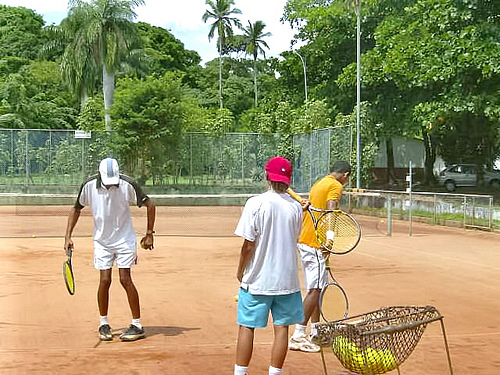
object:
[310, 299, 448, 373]
basket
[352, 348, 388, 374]
tennis balls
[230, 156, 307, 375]
boy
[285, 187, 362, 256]
tennis racket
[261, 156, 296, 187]
cap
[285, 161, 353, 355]
boy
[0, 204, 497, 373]
dirt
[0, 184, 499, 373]
tennis court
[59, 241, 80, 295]
racket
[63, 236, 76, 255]
hand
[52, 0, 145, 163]
tree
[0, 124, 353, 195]
fence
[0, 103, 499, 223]
perimeter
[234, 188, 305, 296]
shirt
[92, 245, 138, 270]
shorts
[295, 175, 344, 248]
shirt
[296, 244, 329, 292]
short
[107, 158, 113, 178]
stripe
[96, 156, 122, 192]
cap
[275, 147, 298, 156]
backwards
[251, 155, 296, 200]
wearing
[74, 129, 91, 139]
sign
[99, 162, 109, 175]
white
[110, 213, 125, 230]
white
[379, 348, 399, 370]
balls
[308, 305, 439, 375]
these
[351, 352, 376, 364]
yellow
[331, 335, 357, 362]
ball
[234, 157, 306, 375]
people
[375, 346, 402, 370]
tennis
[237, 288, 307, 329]
shorts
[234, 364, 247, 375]
socks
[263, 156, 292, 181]
head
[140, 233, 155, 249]
hand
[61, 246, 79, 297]
tennis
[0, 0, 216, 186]
leaves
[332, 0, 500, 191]
trees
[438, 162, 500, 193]
car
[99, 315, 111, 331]
socks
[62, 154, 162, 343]
man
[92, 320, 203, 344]
shadow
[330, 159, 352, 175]
hair